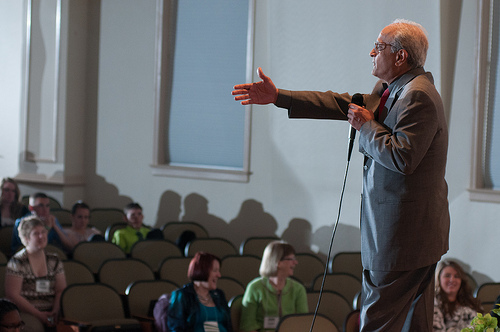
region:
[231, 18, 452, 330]
man holding a microphone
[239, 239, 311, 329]
woman wearing green shirt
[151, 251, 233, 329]
woman sitting on a chair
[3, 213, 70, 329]
woman with short hair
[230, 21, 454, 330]
old man wearing glasses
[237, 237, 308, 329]
woman wearing glasses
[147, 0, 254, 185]
closed window in room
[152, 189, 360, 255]
several shadows on wall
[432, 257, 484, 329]
young woman with long hair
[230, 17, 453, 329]
old man wearing dark suit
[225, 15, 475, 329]
The man is giving a speech.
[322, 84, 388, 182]
The man holds a microphone.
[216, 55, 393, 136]
The man's arm is outstretched.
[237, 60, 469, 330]
The man wears a grey suit.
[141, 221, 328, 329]
People sit in the audience.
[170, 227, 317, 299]
The women are laughing.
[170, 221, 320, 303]
The women are looking to the right.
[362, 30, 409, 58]
The man wears eyeglasses.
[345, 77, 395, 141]
The man wears a red tie.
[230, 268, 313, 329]
The woman wears a green sweater.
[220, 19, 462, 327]
man is giving a speach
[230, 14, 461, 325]
man has right hand extended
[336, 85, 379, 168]
hand holding a black microphone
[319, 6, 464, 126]
man has gray hair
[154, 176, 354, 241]
shadows of heads cast on a wall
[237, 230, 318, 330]
woman wears a green jacket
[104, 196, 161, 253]
boy wearing a green shirt and black tie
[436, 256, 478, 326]
woman is smiling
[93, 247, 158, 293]
chair on room is light brown with dark border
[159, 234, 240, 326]
woman with red hair wears necklaces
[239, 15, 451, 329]
The man is wearing a suit.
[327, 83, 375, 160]
He is holding a microphone.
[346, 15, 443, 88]
He is wearing glasses.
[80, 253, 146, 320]
The seat is empty.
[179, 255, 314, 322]
Two ladies sitting.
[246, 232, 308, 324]
She is wearing a green shirt.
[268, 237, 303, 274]
She is wearing glasses.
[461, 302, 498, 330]
The flowers are yellow.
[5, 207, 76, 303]
She has a name tag on.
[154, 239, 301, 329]
They are talking.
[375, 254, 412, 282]
edge of a coat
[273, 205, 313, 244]
edge of a dhade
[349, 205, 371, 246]
edge of a coat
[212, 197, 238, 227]
part of a shadow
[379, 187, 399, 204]
part of a pocket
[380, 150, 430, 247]
part of an elbow